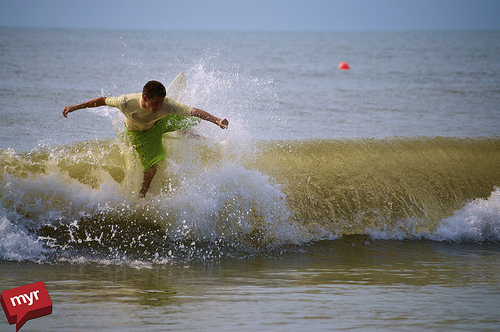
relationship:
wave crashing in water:
[29, 135, 498, 237] [4, 26, 497, 330]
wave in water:
[29, 135, 498, 237] [4, 26, 497, 330]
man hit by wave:
[58, 80, 238, 210] [29, 135, 498, 237]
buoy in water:
[336, 60, 352, 71] [4, 26, 497, 330]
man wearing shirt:
[58, 80, 238, 210] [109, 93, 191, 131]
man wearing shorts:
[58, 80, 238, 210] [125, 123, 204, 155]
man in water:
[58, 80, 238, 210] [4, 26, 497, 330]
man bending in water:
[58, 80, 238, 210] [4, 26, 497, 330]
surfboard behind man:
[156, 69, 210, 197] [58, 80, 238, 210]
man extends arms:
[58, 80, 238, 210] [56, 92, 233, 134]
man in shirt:
[58, 80, 238, 210] [109, 93, 191, 131]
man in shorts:
[58, 80, 238, 210] [125, 123, 204, 155]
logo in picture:
[0, 276, 64, 331] [0, 1, 499, 332]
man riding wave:
[58, 80, 238, 210] [29, 135, 498, 237]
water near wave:
[4, 26, 497, 330] [29, 135, 498, 237]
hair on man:
[140, 79, 169, 99] [58, 80, 238, 210]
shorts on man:
[125, 123, 204, 155] [58, 80, 238, 210]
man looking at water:
[58, 80, 238, 210] [4, 26, 497, 330]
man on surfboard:
[58, 80, 238, 210] [156, 69, 210, 197]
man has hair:
[58, 80, 238, 210] [140, 79, 169, 99]